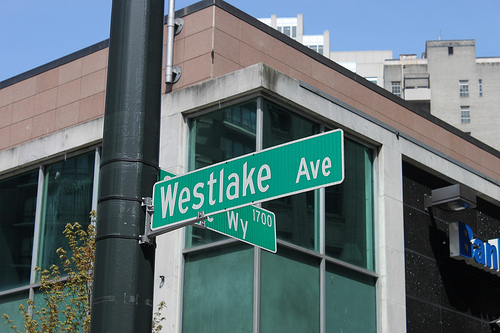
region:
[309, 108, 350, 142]
white border of sign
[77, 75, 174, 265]
black pole by building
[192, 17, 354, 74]
red exterior of building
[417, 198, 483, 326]
marble black exterior of bank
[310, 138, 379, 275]
window of bank of america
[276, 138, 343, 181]
ave print on sign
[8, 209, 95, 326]
tree by the black pole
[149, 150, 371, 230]
westlake ave green sign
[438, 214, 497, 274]
bank of america logo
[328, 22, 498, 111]
building in the back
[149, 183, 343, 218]
Green street sign attached to pole.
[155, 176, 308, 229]
White lettering on green sign.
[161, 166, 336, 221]
Street sign says westlake ave.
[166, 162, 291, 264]
Green street sign behind westlake sign.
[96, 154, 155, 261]
Black bands attaching street signs to pole.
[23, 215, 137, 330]
Tree behind black pole.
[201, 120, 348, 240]
Windows on the corner of building.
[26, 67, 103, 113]
Brown building on corner.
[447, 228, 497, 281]
Blue lettering on side of building.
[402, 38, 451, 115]
Tall gray building in background.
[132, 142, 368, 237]
a street sign says Westlake Ave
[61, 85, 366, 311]
street signs attached to a pole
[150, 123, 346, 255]
green and white street sign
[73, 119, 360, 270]
two streeet signs hanging on a black pole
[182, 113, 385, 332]
windows on the corner of the building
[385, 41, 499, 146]
gray building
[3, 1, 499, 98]
blue sky with no clouds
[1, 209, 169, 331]
skinny tree branches next ot the pole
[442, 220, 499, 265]
blue writing on the side of the building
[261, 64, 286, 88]
black marks on the concrete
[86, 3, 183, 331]
skinny black pole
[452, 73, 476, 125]
two windows on the side of the building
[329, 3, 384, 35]
the sky is clear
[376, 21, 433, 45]
the sky is clear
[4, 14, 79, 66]
the sky is clear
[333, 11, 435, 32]
the sky is clear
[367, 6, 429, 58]
the sky is clear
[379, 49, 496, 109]
the building is gray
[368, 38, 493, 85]
the building is gray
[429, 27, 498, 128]
the building is gray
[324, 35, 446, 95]
the building is gray